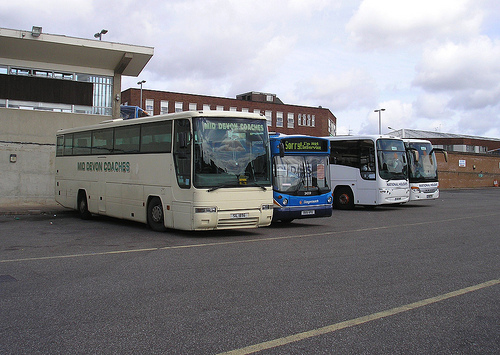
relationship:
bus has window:
[45, 106, 285, 255] [186, 123, 276, 190]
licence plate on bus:
[224, 204, 253, 224] [45, 106, 285, 255]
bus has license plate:
[267, 129, 337, 223] [297, 206, 317, 218]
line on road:
[332, 279, 475, 335] [215, 241, 498, 348]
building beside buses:
[435, 132, 498, 188] [44, 104, 447, 236]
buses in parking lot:
[48, 97, 446, 247] [13, 204, 483, 316]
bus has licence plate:
[267, 129, 337, 223] [295, 204, 318, 216]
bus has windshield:
[45, 106, 285, 255] [190, 115, 279, 193]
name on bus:
[72, 155, 135, 178] [45, 106, 285, 255]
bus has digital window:
[267, 129, 337, 223] [272, 132, 339, 155]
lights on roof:
[88, 23, 117, 39] [2, 37, 162, 77]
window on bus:
[50, 117, 177, 162] [45, 106, 285, 255]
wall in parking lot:
[448, 152, 486, 186] [12, 214, 499, 354]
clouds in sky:
[410, 35, 499, 102] [6, 1, 498, 111]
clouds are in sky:
[243, 9, 471, 81] [278, 30, 466, 98]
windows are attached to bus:
[49, 115, 186, 160] [45, 106, 285, 255]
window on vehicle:
[81, 129, 135, 149] [83, 101, 305, 242]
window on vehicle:
[273, 164, 338, 204] [243, 122, 388, 259]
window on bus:
[91, 128, 171, 161] [48, 112, 303, 251]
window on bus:
[131, 108, 188, 162] [65, 107, 274, 235]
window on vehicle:
[135, 117, 178, 155] [45, 108, 279, 238]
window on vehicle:
[185, 109, 276, 192] [45, 108, 279, 238]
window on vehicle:
[170, 114, 194, 187] [45, 108, 279, 238]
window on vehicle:
[111, 117, 151, 157] [45, 108, 279, 238]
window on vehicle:
[84, 127, 114, 160] [45, 108, 279, 238]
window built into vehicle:
[62, 132, 73, 155] [45, 108, 279, 238]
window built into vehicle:
[377, 136, 408, 180] [326, 132, 411, 209]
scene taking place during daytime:
[1, 1, 484, 350] [1, 1, 482, 352]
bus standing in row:
[45, 106, 285, 255] [51, 108, 448, 234]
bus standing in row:
[267, 129, 337, 223] [51, 108, 448, 234]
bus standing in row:
[328, 130, 420, 208] [51, 108, 448, 234]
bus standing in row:
[403, 137, 450, 203] [51, 108, 448, 234]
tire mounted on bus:
[75, 189, 90, 219] [45, 106, 285, 255]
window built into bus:
[135, 117, 178, 155] [45, 106, 285, 255]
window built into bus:
[112, 124, 141, 154] [45, 106, 285, 255]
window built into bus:
[84, 127, 114, 160] [45, 106, 285, 255]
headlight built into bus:
[194, 205, 216, 213] [45, 106, 285, 255]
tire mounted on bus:
[146, 196, 165, 230] [45, 106, 285, 255]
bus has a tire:
[45, 106, 285, 255] [69, 189, 96, 229]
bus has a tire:
[45, 106, 285, 255] [61, 189, 92, 219]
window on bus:
[131, 108, 188, 162] [38, 98, 275, 244]